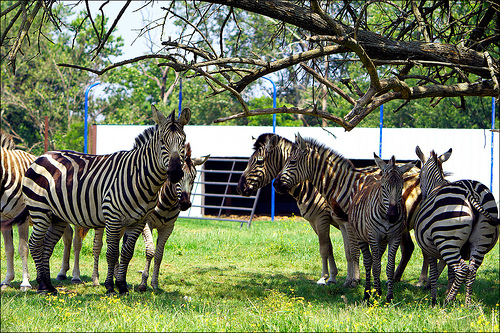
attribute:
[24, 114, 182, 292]
zebra — black, striped, white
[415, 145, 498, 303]
zebra — black, striped, white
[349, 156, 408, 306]
zebra — black, striped, white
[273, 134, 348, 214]
zebra — striped, black, white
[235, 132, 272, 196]
zebra — black, striped, white